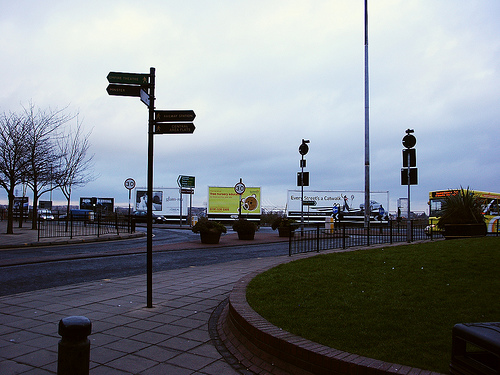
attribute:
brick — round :
[129, 329, 174, 350]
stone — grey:
[89, 289, 206, 368]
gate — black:
[277, 201, 465, 266]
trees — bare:
[10, 129, 118, 211]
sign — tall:
[164, 160, 202, 192]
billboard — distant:
[134, 186, 191, 218]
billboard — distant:
[202, 184, 264, 216]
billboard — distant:
[280, 186, 391, 222]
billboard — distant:
[78, 195, 118, 218]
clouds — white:
[50, 14, 422, 154]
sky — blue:
[7, 3, 488, 215]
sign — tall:
[387, 126, 449, 215]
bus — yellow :
[426, 188, 498, 234]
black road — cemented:
[9, 252, 144, 279]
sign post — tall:
[97, 68, 197, 305]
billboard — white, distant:
[286, 187, 390, 223]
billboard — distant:
[192, 181, 275, 227]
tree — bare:
[49, 131, 99, 226]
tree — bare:
[7, 96, 66, 226]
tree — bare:
[1, 127, 26, 229]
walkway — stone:
[0, 244, 296, 373]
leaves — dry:
[31, 169, 55, 180]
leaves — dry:
[14, 155, 27, 170]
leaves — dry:
[0, 159, 10, 176]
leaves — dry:
[8, 130, 15, 138]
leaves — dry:
[38, 149, 48, 155]